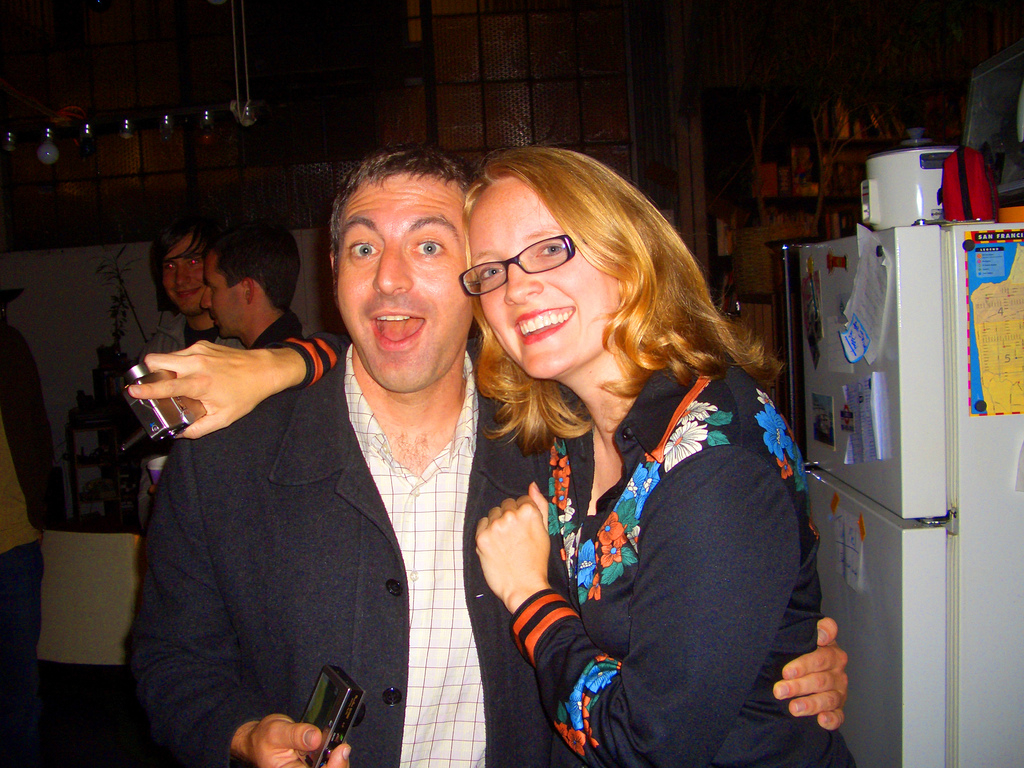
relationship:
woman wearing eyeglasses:
[124, 142, 845, 760] [462, 222, 603, 292]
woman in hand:
[124, 142, 845, 760] [145, 310, 282, 432]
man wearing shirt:
[124, 145, 564, 766] [321, 340, 522, 760]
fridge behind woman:
[797, 219, 1024, 768] [123, 148, 863, 768]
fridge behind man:
[797, 219, 1024, 768] [124, 145, 564, 766]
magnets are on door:
[805, 383, 837, 444] [785, 222, 945, 760]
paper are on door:
[841, 370, 882, 465] [785, 222, 945, 760]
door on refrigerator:
[785, 222, 945, 760] [773, 218, 1012, 765]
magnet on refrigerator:
[952, 220, 1022, 437] [773, 218, 1012, 765]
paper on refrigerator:
[832, 361, 893, 466] [773, 218, 1012, 765]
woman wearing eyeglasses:
[123, 148, 863, 768] [460, 234, 577, 295]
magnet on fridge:
[952, 220, 1022, 437] [773, 214, 1011, 759]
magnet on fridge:
[808, 345, 861, 413] [773, 214, 1011, 759]